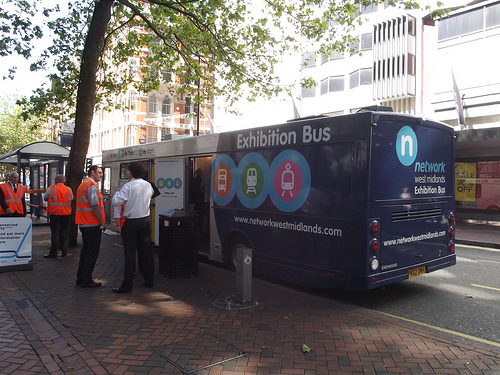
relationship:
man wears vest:
[73, 165, 105, 287] [71, 176, 104, 227]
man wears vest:
[46, 175, 72, 259] [49, 184, 73, 215]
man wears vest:
[3, 176, 34, 267] [0, 180, 27, 212]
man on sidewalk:
[73, 165, 105, 287] [2, 208, 499, 370]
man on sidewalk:
[116, 166, 157, 294] [2, 208, 499, 370]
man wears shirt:
[116, 166, 157, 294] [114, 176, 157, 219]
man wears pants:
[116, 166, 157, 294] [123, 221, 154, 290]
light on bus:
[368, 222, 380, 235] [99, 112, 455, 297]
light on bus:
[370, 239, 382, 249] [99, 112, 455, 297]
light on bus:
[369, 259, 380, 270] [99, 112, 455, 297]